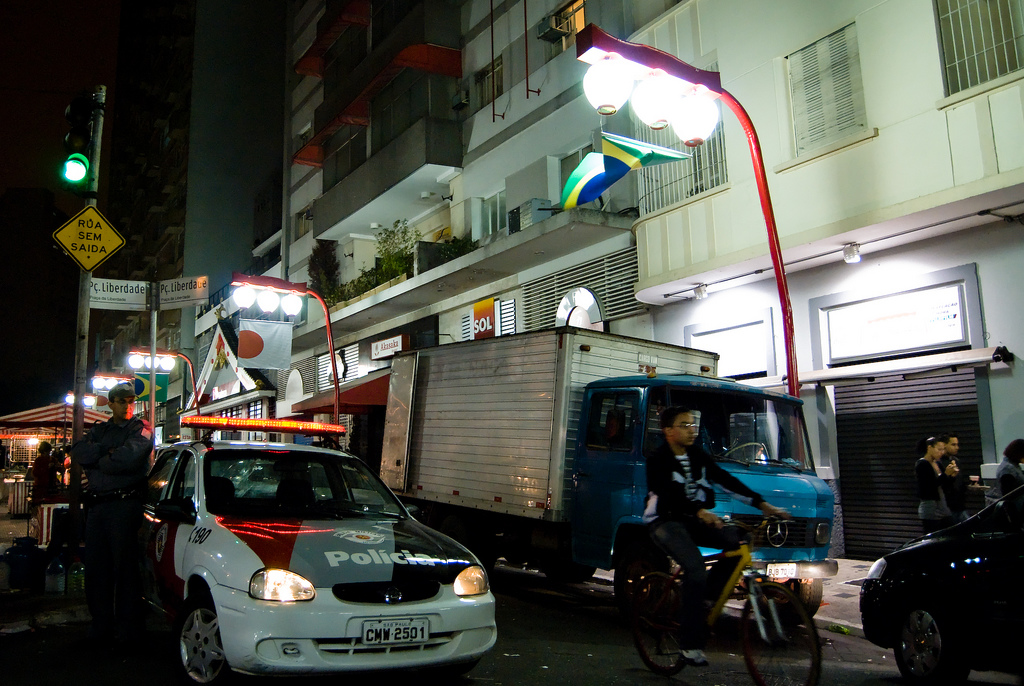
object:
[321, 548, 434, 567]
scene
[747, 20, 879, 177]
window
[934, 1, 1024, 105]
window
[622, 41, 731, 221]
window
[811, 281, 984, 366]
window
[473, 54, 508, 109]
window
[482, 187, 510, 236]
window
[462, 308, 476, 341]
window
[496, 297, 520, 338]
window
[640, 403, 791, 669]
man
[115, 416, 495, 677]
car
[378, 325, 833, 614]
van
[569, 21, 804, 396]
streetlight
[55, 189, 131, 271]
streetsign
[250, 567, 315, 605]
headlight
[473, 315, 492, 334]
sign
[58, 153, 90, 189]
stoplight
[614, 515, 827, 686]
bike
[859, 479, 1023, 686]
sedan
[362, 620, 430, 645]
licenseplate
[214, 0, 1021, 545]
building